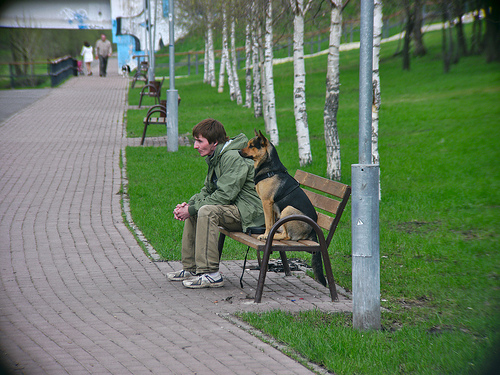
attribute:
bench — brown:
[135, 90, 187, 148]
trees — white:
[394, 3, 499, 116]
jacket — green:
[190, 139, 265, 227]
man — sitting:
[164, 116, 266, 289]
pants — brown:
[199, 210, 246, 263]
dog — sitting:
[238, 131, 318, 241]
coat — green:
[186, 133, 277, 232]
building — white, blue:
[108, 2, 171, 58]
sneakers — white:
[171, 267, 230, 294]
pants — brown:
[176, 199, 271, 295]